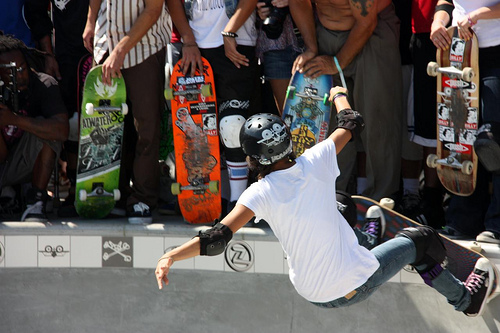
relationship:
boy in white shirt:
[149, 78, 500, 320] [234, 132, 385, 306]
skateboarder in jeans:
[149, 78, 500, 320] [312, 221, 476, 316]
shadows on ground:
[2, 210, 439, 333] [3, 210, 499, 333]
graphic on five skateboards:
[82, 109, 117, 172] [74, 64, 130, 220]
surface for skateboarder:
[3, 210, 499, 333] [155, 78, 500, 319]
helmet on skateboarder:
[237, 112, 300, 169] [149, 78, 500, 320]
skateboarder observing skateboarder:
[155, 78, 500, 319] [149, 78, 500, 320]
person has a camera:
[247, 2, 303, 115] [253, 1, 291, 42]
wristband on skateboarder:
[329, 90, 349, 103] [149, 78, 500, 320]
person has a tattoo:
[285, 1, 406, 210] [351, 1, 373, 18]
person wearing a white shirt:
[428, 0, 499, 242] [446, 1, 500, 55]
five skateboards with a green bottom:
[74, 64, 130, 220] [85, 67, 117, 212]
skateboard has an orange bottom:
[164, 52, 229, 233] [168, 52, 226, 228]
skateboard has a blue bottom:
[278, 54, 336, 161] [282, 61, 334, 158]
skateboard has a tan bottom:
[425, 22, 484, 202] [436, 26, 479, 201]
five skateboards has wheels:
[74, 64, 130, 220] [79, 102, 128, 204]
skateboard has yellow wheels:
[164, 52, 229, 233] [157, 83, 223, 197]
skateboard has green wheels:
[278, 54, 336, 161] [280, 81, 333, 112]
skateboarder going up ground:
[149, 78, 500, 320] [3, 210, 499, 333]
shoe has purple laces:
[357, 204, 386, 245] [363, 218, 381, 234]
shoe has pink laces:
[459, 255, 493, 321] [464, 271, 488, 297]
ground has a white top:
[3, 210, 499, 333] [0, 230, 500, 280]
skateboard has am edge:
[341, 191, 500, 308] [350, 195, 480, 260]